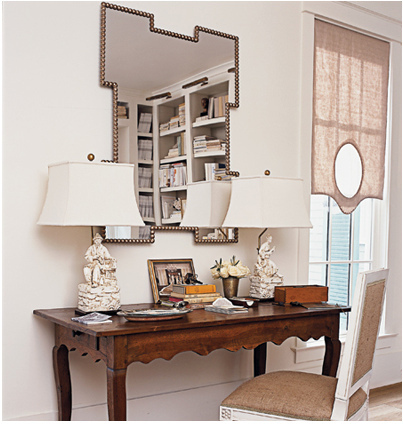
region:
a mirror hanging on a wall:
[78, 23, 247, 192]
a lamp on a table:
[240, 172, 316, 303]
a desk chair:
[197, 259, 390, 419]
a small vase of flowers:
[209, 249, 249, 298]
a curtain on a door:
[285, 29, 393, 210]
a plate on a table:
[109, 291, 190, 329]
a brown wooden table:
[12, 285, 346, 411]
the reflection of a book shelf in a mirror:
[135, 56, 247, 159]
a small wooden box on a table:
[255, 282, 337, 315]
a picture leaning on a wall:
[134, 252, 204, 301]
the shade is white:
[34, 154, 153, 249]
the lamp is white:
[30, 138, 151, 333]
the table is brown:
[39, 267, 363, 420]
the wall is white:
[15, 19, 80, 119]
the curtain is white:
[308, 10, 398, 189]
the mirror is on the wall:
[86, 2, 247, 253]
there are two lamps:
[28, 126, 331, 332]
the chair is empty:
[210, 248, 394, 416]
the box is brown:
[264, 272, 335, 304]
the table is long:
[33, 272, 363, 362]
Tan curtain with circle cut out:
[310, 13, 392, 215]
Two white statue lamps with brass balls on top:
[34, 152, 312, 315]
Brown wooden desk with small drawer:
[31, 294, 351, 422]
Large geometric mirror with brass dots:
[99, 1, 238, 244]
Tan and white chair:
[217, 265, 390, 418]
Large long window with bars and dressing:
[291, 14, 398, 364]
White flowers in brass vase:
[208, 254, 250, 299]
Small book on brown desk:
[70, 309, 113, 325]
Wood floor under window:
[356, 373, 402, 422]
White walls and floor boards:
[4, 1, 399, 418]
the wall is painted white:
[1, 1, 399, 417]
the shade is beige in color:
[316, 16, 386, 216]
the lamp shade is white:
[40, 160, 145, 229]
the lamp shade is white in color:
[226, 176, 312, 230]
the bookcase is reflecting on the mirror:
[145, 55, 233, 224]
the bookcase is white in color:
[144, 60, 237, 218]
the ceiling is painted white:
[102, 5, 237, 97]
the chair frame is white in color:
[223, 263, 389, 416]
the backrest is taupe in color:
[350, 279, 384, 381]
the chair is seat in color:
[219, 368, 364, 416]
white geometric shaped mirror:
[66, 5, 254, 235]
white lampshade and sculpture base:
[41, 148, 150, 320]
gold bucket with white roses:
[223, 273, 255, 302]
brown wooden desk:
[55, 300, 335, 367]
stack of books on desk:
[173, 281, 223, 314]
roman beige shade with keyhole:
[306, 17, 391, 224]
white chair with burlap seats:
[240, 235, 401, 414]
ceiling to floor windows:
[318, 204, 387, 308]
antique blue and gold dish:
[106, 304, 189, 323]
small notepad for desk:
[203, 297, 243, 314]